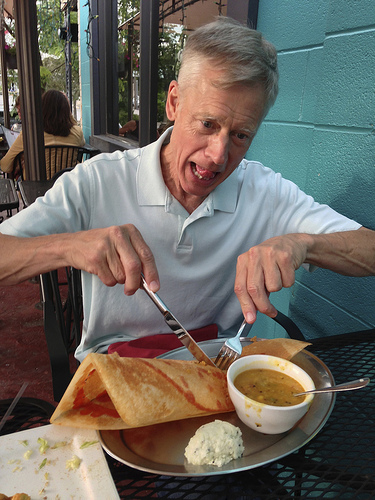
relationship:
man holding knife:
[10, 24, 374, 438] [136, 272, 230, 373]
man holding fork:
[10, 24, 374, 438] [210, 316, 260, 366]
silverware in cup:
[294, 377, 374, 399] [226, 352, 312, 430]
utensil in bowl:
[294, 375, 367, 394] [227, 356, 315, 429]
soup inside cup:
[236, 369, 309, 404] [226, 352, 312, 430]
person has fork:
[10, 24, 374, 438] [210, 316, 260, 366]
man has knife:
[0, 14, 374, 364] [136, 272, 230, 373]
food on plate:
[70, 341, 317, 458] [89, 330, 332, 476]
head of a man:
[163, 24, 280, 189] [10, 24, 374, 438]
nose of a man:
[207, 124, 234, 167] [10, 24, 374, 438]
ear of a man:
[163, 80, 184, 114] [10, 24, 374, 438]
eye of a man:
[196, 117, 216, 128] [10, 24, 374, 438]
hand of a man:
[65, 220, 157, 286] [10, 24, 374, 438]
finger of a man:
[115, 233, 140, 294] [10, 24, 374, 438]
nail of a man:
[148, 282, 160, 293] [10, 24, 374, 438]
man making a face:
[10, 24, 374, 438] [167, 46, 256, 187]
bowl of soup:
[227, 356, 315, 429] [236, 369, 309, 404]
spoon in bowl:
[294, 377, 374, 399] [227, 356, 315, 429]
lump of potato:
[185, 416, 247, 468] [183, 419, 241, 464]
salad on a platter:
[189, 422, 242, 467] [89, 330, 332, 476]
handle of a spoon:
[293, 377, 370, 395] [296, 380, 361, 400]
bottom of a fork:
[215, 336, 249, 365] [210, 316, 260, 366]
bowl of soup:
[227, 354, 317, 435] [226, 352, 312, 430]